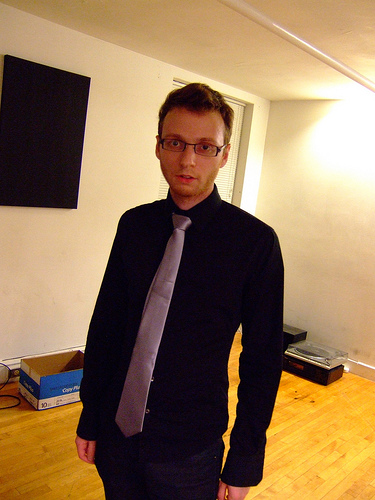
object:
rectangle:
[0, 53, 86, 214]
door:
[231, 100, 262, 204]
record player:
[280, 336, 346, 385]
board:
[0, 55, 93, 208]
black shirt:
[74, 190, 284, 485]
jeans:
[95, 437, 225, 498]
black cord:
[0, 358, 21, 412]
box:
[17, 351, 86, 410]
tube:
[218, 0, 373, 90]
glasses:
[152, 128, 230, 159]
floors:
[0, 326, 375, 497]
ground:
[280, 463, 313, 500]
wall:
[250, 79, 374, 247]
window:
[169, 80, 247, 208]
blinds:
[172, 75, 254, 206]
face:
[157, 105, 225, 197]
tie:
[113, 209, 192, 440]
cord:
[2, 391, 24, 411]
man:
[75, 81, 283, 494]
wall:
[3, 3, 267, 401]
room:
[0, 3, 372, 496]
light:
[318, 108, 369, 174]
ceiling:
[14, 0, 371, 103]